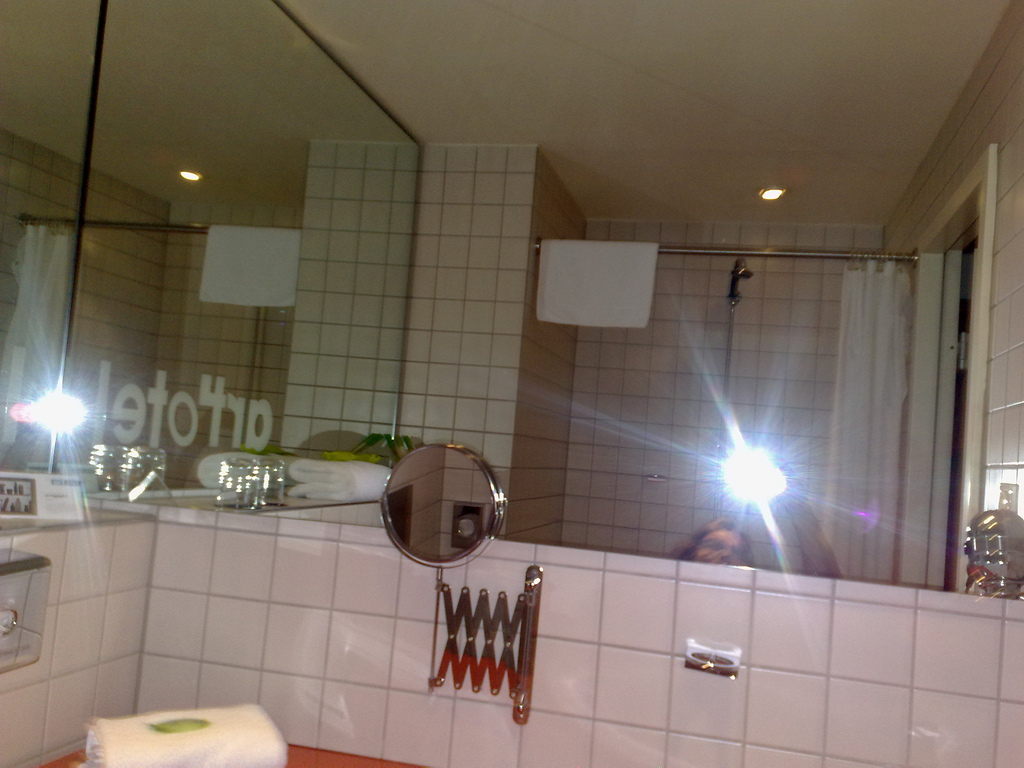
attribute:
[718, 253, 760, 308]
shower — head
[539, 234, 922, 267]
rod — shower, curtain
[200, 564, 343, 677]
tile — white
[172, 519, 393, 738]
wall — bathroom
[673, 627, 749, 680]
dish — silver, soap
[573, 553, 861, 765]
wall — tile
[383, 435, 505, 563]
mirror — small, circle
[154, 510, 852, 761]
wall — white, clean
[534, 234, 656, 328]
towel — white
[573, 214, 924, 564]
area — shower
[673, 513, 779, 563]
person — white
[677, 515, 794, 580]
person — refelction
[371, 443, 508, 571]
mirror — circular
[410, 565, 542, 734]
holder — metal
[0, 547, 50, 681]
tissue box — silver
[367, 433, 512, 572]
mirror — small, circular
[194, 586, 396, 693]
tiles — pink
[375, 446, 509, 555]
mirror — small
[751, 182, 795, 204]
circle — small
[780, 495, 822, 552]
arm — raised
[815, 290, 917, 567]
curtains — shower